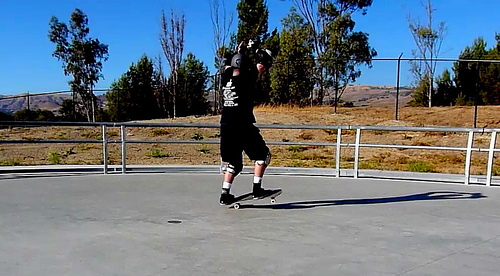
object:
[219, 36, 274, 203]
person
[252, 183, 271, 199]
black shoe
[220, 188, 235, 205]
black shoe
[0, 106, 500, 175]
dirt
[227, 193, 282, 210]
board